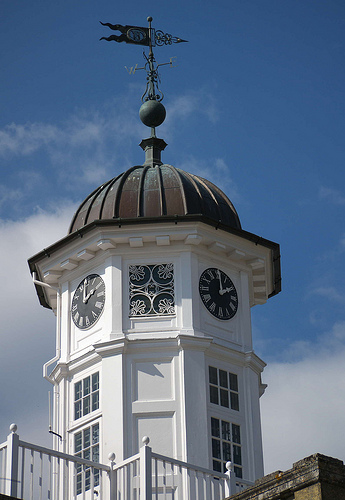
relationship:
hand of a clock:
[82, 278, 87, 304] [69, 273, 105, 330]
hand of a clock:
[82, 278, 96, 304] [69, 273, 105, 330]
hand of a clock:
[216, 271, 233, 295] [198, 267, 238, 322]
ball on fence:
[136, 430, 177, 453] [118, 453, 225, 498]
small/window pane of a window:
[208, 365, 240, 411] [208, 362, 242, 412]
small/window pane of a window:
[222, 420, 232, 438] [204, 361, 241, 411]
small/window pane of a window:
[208, 382, 221, 405] [204, 361, 244, 414]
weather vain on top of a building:
[98, 12, 190, 99] [3, 126, 331, 497]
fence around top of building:
[0, 424, 254, 500] [26, 143, 280, 499]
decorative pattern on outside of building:
[129, 262, 174, 314] [26, 163, 283, 464]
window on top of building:
[75, 370, 99, 495] [25, 138, 280, 496]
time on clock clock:
[80, 277, 104, 303] [66, 271, 105, 329]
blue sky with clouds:
[16, 21, 338, 237] [4, 205, 54, 424]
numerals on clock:
[72, 299, 92, 327] [69, 273, 105, 330]